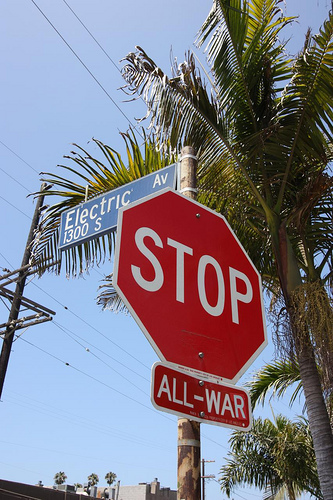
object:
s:
[128, 223, 172, 297]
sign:
[110, 194, 258, 373]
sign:
[161, 363, 253, 419]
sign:
[47, 175, 193, 236]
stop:
[120, 224, 257, 333]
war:
[208, 392, 246, 422]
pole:
[177, 153, 206, 499]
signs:
[78, 148, 252, 421]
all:
[147, 372, 192, 407]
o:
[192, 243, 227, 320]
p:
[227, 266, 257, 327]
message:
[141, 372, 251, 424]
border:
[109, 207, 126, 285]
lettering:
[120, 231, 258, 317]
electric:
[48, 188, 131, 217]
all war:
[157, 372, 254, 418]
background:
[2, 9, 331, 470]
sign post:
[172, 154, 224, 494]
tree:
[204, 2, 331, 500]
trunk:
[277, 284, 331, 432]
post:
[4, 175, 44, 355]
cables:
[32, 310, 146, 414]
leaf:
[263, 364, 288, 382]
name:
[62, 181, 134, 220]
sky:
[8, 8, 159, 152]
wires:
[44, 5, 157, 129]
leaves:
[217, 8, 326, 222]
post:
[174, 144, 193, 495]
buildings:
[0, 462, 197, 499]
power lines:
[65, 318, 143, 381]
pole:
[2, 172, 51, 392]